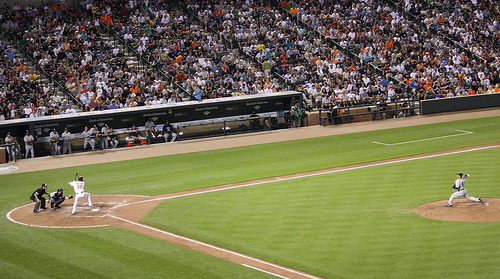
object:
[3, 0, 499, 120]
crowd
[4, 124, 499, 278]
field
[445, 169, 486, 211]
pitcher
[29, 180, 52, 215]
umpire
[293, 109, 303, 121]
shirt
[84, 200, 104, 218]
homeplate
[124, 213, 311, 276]
chalk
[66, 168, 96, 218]
baseball player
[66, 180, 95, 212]
uniform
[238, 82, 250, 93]
spectators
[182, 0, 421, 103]
stands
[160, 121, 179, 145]
players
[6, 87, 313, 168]
dugout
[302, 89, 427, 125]
fence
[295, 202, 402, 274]
grass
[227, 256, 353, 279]
lines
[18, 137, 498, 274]
dirt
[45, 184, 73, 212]
catcher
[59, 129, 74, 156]
players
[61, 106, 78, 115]
people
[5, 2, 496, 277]
stadium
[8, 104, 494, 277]
game